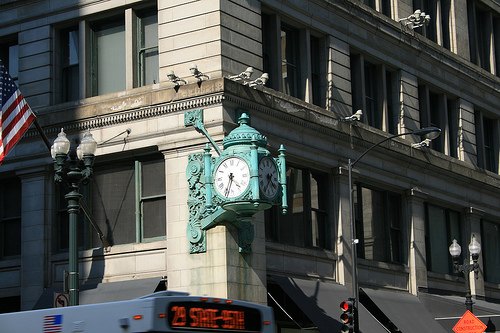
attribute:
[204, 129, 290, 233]
clock — black, green, here, moulded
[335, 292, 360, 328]
light — red, lamp street, 2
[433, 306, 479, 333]
sign — orange, white, no left turn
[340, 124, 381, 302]
pole — black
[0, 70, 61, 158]
flag — national, american, hanging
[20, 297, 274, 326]
bus — white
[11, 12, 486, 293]
building — brown, tan, here, large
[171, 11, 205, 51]
stone — grey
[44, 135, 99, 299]
lamp — metal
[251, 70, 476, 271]
window — here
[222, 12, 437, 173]
wall — here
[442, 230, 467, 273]
light — 2, lamp street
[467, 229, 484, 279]
light — 2, lamp street